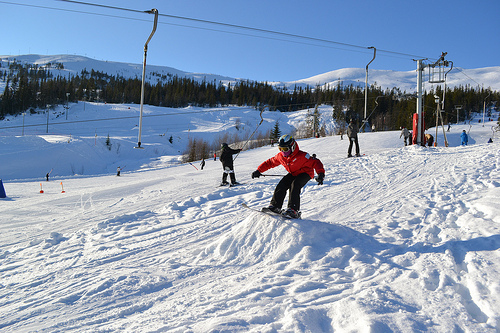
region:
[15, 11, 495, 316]
people participating in snow activities at park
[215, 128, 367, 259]
snowboarder on small ramp made of snow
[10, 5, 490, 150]
elevated wires with hanging poles and disks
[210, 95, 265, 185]
person hanging onto pole and being moved on snow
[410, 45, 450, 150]
metal support next to elevated railed platform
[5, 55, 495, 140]
row of evergreen trees at edge of slopes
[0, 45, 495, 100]
snow-covered mountains behind trees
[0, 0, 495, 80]
clear and bright blue sky behind mountains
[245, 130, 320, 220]
snowboarder with knees bent leaning forwar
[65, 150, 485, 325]
snow covered with footprints and lines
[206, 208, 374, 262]
A small mound of snow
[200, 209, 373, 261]
A small snow brim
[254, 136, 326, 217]
A man on snow skies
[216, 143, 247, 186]
A man standing in the snow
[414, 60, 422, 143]
A tall metal pole holding up a ski lift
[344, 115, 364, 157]
A person in dark clothing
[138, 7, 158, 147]
A part of a ski lift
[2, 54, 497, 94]
A large range of mountains off in the distance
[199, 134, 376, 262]
A person sking up a small mound of snow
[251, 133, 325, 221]
A person wearing a red jacket skiing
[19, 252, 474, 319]
the ground is covered in snow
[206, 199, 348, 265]
a small slope for practice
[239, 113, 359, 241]
person practices skiing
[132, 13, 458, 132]
a portion of the ski lift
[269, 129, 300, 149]
the person is wearing a helmet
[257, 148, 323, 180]
the person is wearing a red jacket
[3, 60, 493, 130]
many trees can be seen in the background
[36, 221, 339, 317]
the snow on the ground is white in color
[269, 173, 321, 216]
the person is wearing black snow pants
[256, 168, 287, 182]
the person's ski pole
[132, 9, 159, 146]
A empty ski lift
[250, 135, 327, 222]
A person skiing in the snow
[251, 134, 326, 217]
A person skiing over a small brim of snow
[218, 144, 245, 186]
A person wearing a black jacket and snow skies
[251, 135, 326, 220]
A person wearing a red jacket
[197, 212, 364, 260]
A mall mound of snow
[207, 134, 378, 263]
A man with a red jacket skiing up a small mound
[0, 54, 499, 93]
A view of the mountains out on the horizon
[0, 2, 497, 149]
A large length of ski lift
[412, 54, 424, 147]
A large tall pole holding up a ski lift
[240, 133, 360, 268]
a person in a red jacket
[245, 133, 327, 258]
a person jumping over a mound of snow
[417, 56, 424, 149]
a metal post in the snow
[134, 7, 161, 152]
a pole hanging from a wire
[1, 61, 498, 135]
trees in the far distance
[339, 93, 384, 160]
a man hanging a pole on a wire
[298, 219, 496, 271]
a shadow on the snow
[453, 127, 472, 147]
a person with a blue jacket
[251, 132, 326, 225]
a man wearing goggles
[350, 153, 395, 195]
tracks in the snow